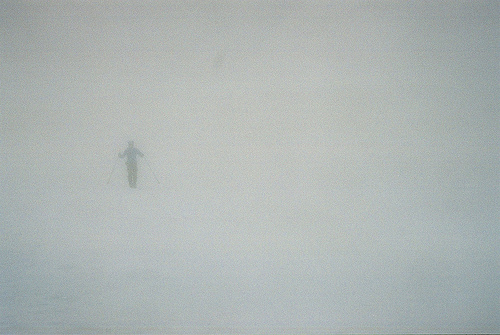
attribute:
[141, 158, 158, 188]
stick — ski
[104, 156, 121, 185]
stick — ski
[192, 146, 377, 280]
patch — big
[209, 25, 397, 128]
flurry — big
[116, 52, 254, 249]
field —  foggy day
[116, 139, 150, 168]
arm — person's outstretched 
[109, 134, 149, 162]
arm — person's outstretched 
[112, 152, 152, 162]
hand — person's 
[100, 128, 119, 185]
pole — ski 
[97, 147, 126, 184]
pole — ski 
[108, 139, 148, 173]
hand — person's 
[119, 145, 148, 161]
jacket — dark 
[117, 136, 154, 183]
person — blurry 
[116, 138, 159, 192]
person — blurry 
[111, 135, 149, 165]
arms — open 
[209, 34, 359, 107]
mist — blurry white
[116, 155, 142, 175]
outfit — black 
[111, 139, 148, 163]
arms — open  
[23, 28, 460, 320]
scene — white 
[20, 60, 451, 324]
picture — blurry 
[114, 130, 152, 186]
person — standing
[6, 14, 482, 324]
image — blurry 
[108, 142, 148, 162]
arms — open 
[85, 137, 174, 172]
poles — snow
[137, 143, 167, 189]
pole — snow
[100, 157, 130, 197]
pole — snow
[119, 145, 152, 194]
clothes — black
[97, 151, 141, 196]
poles — snow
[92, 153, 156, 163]
poles — skiing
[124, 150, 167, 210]
clothes — dark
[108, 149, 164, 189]
clothes — dark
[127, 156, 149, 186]
clothes — dark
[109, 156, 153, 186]
poles — skiing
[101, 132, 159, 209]
person — clothes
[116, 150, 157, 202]
clothes — skiing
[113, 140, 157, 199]
person — alone